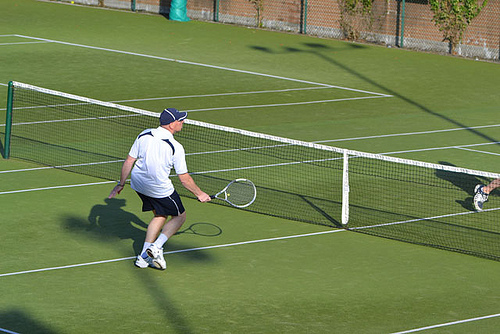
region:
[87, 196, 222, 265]
shadow of a tennis player and his racket on a tennis court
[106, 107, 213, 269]
man wearing a blue hat and white shirt playing tennis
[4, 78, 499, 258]
tennis net found on a court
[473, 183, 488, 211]
dark blue right tennis shoe worn by a tennis player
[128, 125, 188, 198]
white T-shirt with a dark color design above shoulder blades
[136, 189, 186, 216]
pair of black shorts with white stripe running down the sides worn by a player of tennis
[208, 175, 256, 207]
tennis racket being held by a player preparing to hit a ball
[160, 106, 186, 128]
dark blue hat worn by a tennis player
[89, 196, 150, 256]
shadow of a man on a tennis court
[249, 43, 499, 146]
shadow of a light pole found on a tennis court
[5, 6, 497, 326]
man in a blue hat playing tennis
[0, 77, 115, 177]
net on the tennis court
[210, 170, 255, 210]
silver tennis racket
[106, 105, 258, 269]
man wearing blue hat, white shirt and black shorts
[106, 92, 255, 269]
tennis player in blue hat holding tennis racket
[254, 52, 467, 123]
green turf with white lines of tennis court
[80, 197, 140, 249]
shadow of tennis player on green turf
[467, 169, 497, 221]
part of leg and sneaker of a person on the tennis court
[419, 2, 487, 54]
green ivy on the outer fence of tennis court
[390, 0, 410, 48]
dark green pole of out tennis court fence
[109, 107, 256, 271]
a man playing tennis on a tennis court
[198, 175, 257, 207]
a man holding a tennis racket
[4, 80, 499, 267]
a tennis court net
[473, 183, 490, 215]
a white and blue shoe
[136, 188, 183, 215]
man wearing blue shorts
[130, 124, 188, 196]
man wearing a white shirt with a blue line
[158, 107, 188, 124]
blue cap with a white line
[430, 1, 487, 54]
a small green tree against a brick wall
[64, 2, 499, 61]
a brick wall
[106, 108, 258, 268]
a man ready to play tennis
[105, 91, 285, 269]
a man playing tennis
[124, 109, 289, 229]
a man holding a tennis racket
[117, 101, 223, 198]
a man with a white shirt on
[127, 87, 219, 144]
a man wearing a blue hat on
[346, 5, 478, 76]
a brick wall near a tennis court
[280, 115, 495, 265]
a tennis net on a tennis court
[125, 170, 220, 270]
a man wearing tennis shoes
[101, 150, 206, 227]
a man wearing blue shorts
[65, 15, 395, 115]
white lines on a tennis court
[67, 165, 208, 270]
a man shadow on the ground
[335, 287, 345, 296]
part of a court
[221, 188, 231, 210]
part of a racket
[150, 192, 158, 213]
part of a short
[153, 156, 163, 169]
part of a shirt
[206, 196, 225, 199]
part of a wheel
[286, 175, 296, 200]
edge of a net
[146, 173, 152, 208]
back of a man